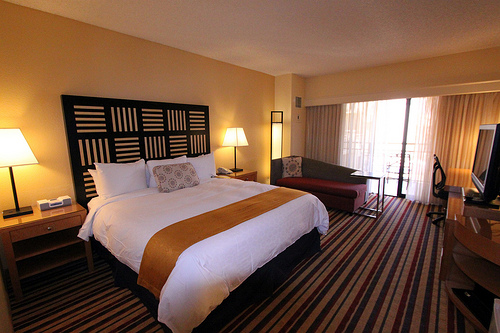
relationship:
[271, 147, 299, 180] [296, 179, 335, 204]
pillow on chair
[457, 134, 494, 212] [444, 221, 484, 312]
television on stand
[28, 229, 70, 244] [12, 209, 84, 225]
box on table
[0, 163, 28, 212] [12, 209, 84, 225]
lamps are on table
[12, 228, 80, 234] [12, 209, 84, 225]
drawer in front of table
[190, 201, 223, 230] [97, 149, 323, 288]
line on bed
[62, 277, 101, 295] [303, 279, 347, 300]
stripes are on carpeting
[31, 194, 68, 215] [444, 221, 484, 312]
clock on stand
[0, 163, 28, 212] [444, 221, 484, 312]
lamps are on stand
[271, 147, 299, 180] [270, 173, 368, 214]
pillow on chair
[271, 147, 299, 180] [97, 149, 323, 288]
pillow on top of bed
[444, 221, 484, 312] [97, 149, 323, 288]
stand beside bed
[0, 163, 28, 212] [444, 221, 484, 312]
lamps are on top of stand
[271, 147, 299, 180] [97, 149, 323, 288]
pillow on bed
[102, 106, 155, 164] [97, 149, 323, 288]
headboard on bed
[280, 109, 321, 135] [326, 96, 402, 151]
blinds are over window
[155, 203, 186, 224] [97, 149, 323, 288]
blanket covering bed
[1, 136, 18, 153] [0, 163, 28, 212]
light on lamps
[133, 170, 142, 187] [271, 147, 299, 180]
case on pillow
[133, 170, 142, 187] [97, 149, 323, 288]
case on bed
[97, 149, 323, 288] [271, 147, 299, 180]
bed has a pillow